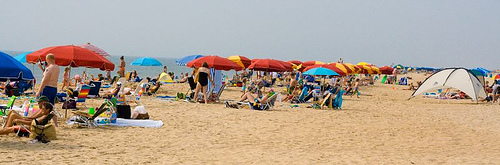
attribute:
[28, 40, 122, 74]
umbrella — open, large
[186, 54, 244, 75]
umbrella — large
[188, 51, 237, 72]
umbrella — large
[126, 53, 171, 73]
umbrella — large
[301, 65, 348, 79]
umbrella — large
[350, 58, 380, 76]
umbrella — large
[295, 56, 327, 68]
umbrella — large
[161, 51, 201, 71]
umbrella — large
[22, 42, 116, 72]
umbrella — large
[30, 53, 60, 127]
person — standing up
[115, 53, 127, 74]
person — standing up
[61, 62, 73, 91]
person — sitting down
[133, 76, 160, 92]
person — sitting down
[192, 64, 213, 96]
person — standing up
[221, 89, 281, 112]
person — sitting down